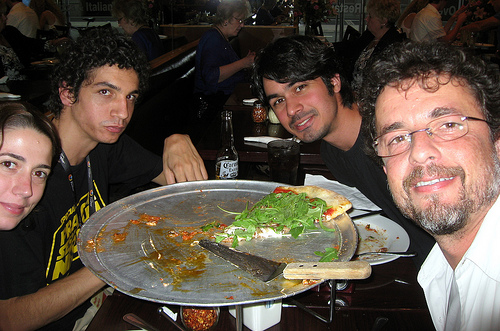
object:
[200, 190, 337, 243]
basil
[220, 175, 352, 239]
pizza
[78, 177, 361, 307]
pan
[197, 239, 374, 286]
spatula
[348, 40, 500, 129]
hair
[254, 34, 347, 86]
hair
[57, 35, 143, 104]
hair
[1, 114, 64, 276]
woman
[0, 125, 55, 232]
face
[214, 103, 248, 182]
bottle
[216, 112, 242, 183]
beer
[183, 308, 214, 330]
pepper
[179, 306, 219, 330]
jar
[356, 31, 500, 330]
man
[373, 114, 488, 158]
glasses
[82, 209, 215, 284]
pizza sauce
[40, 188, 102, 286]
writing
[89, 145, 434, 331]
table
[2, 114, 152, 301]
shirt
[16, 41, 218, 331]
man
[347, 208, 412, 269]
plate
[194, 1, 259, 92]
woman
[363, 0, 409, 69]
women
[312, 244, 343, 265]
lettuce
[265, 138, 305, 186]
cup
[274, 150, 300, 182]
water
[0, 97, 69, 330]
people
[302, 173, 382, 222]
napkins